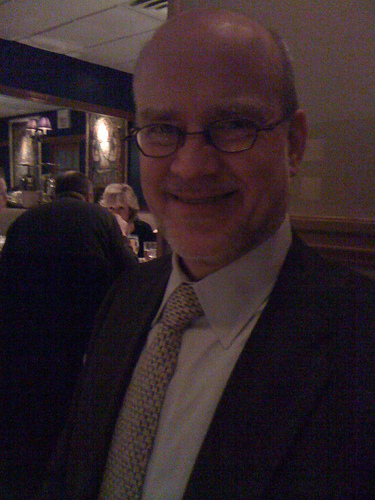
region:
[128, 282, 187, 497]
man is wearing a tie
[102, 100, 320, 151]
man has on glasses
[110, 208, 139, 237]
woman has napkin in her face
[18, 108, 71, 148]
two lights on the wall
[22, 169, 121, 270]
back of man at the table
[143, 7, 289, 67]
man balding on top of head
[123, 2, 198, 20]
vent in the ceiling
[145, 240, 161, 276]
glass of water on table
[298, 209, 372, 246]
trim along the wall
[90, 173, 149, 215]
woman has light colored hair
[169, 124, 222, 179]
the nose on the man's face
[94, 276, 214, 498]
the man's long tie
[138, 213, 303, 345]
the collar on the man's shirt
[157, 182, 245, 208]
the mouth on the man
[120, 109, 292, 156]
the glasses on the man's face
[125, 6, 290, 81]
the bald part of the man's head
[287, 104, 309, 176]
the man's left ear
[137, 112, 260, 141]
the man's two eyes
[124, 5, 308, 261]
the man's whole head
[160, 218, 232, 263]
the man's chin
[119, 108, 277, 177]
Man is wearing glasses.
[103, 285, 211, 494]
Man is wearing a tie.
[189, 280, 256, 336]
The shirt is white.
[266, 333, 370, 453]
The jacket is black.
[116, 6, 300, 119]
The man is balding.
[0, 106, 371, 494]
Taken at a restaurant.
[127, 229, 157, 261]
Glasses on the table.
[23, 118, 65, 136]
Lights on the wall.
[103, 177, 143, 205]
The woman is a blonde.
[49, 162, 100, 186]
Bald spot on the back of the head.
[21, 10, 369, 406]
a man that is bald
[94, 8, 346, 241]
a man wearing glasses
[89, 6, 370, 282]
a man wearing wire glasses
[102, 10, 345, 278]
a man that is smiling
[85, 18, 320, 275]
a man with a smile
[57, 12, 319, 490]
a man wearing a tie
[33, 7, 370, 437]
a man wearing a white shirt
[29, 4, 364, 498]
a man wearing a suit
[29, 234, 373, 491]
a tie and suit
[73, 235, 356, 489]
a suit and tie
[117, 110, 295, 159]
person wearing led framed glasses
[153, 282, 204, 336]
the knot on a multi colored tie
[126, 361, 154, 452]
A multi colored tie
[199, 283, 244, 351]
The collar of a lavender shirt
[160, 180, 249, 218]
a nice big smile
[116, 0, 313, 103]
A head with no hair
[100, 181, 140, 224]
A woman in the background with white hair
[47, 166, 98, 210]
The back of a man's head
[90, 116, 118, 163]
A light reflection on a picture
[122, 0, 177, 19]
A white ceiling vent